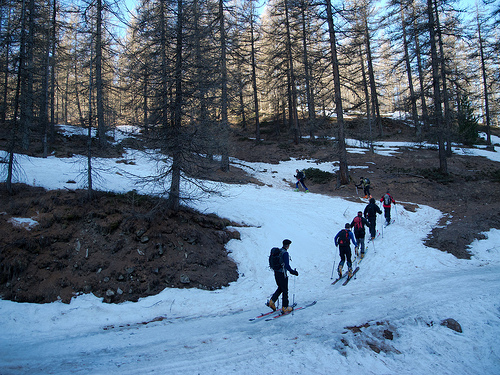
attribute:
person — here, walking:
[265, 238, 299, 314]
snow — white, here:
[0, 124, 499, 374]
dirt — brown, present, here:
[1, 180, 262, 302]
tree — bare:
[133, 0, 226, 206]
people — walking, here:
[266, 168, 398, 315]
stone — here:
[179, 274, 191, 285]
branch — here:
[179, 173, 238, 205]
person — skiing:
[293, 169, 310, 193]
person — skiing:
[355, 176, 374, 200]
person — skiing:
[378, 190, 395, 224]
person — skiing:
[364, 198, 382, 239]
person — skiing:
[351, 211, 371, 261]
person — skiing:
[334, 223, 358, 278]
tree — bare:
[305, 1, 373, 184]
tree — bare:
[398, 0, 468, 176]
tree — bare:
[267, 2, 323, 129]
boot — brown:
[282, 306, 293, 313]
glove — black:
[292, 268, 298, 278]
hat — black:
[281, 239, 291, 246]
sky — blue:
[0, 0, 498, 78]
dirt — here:
[293, 145, 499, 262]